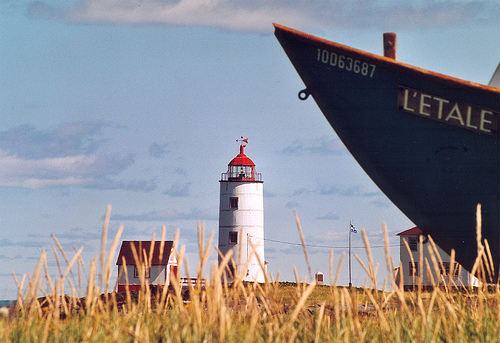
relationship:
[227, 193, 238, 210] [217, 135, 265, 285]
windows on light house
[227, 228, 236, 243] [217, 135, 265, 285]
windows on light house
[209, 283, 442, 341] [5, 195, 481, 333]
grass on field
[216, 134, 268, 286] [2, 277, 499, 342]
light house on field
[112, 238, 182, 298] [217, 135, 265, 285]
house next to light house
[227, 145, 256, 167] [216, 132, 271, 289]
roof of light house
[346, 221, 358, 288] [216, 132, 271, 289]
flag near light house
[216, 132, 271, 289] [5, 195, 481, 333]
light house in field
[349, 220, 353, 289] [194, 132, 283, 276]
flagpole near light house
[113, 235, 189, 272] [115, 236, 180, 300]
roof of house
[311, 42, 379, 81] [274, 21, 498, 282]
serial number of boat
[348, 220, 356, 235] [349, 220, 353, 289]
flag on flagpole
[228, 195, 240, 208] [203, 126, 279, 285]
window on lighthouse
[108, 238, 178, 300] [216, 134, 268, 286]
building by light house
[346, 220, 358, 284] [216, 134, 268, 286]
flagpole near light house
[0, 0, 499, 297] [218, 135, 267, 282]
sky above lighthouse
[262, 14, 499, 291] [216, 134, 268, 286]
boat near light house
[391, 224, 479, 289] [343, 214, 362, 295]
house front flagpole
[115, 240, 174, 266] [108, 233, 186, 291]
roof on building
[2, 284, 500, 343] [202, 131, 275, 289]
grass around lighthouse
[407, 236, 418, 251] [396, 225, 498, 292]
window on house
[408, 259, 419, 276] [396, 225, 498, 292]
window on house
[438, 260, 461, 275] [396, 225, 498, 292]
window on house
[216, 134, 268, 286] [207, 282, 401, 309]
light house on hill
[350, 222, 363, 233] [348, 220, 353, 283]
flag flying on top of flagpole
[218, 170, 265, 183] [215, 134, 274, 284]
railing on top of light house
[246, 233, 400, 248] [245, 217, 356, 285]
power line hanging between poles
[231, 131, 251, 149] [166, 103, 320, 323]
weather vein on top of light house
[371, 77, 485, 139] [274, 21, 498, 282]
paint on boat